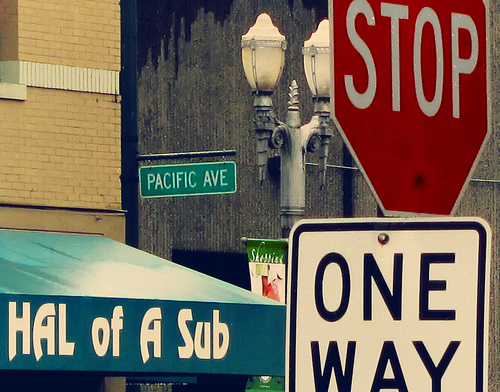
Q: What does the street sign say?
A: Pacific ave.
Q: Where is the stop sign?
A: Above the one way sign.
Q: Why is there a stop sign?
A: Traffic safety.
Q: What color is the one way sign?
A: Black and white.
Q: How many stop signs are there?
A: One.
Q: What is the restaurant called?
A: Hal of a sub.